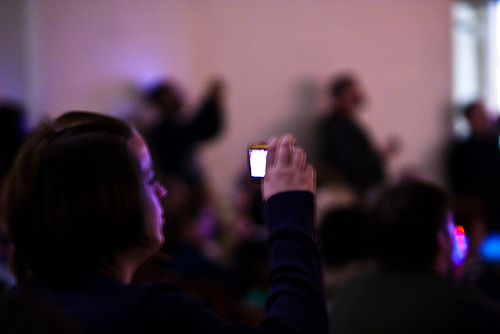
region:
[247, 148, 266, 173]
light from a camera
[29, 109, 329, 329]
a person holding a camera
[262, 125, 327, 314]
a person's hand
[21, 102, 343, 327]
a person standing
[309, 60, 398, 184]
a person standing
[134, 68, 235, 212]
a person standing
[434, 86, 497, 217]
a person standing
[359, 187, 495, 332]
a person standing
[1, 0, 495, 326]
it is a nighttime scene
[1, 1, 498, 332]
the picture is blurry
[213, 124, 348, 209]
The lady is taking a selfie.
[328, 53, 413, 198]
A man is leaning against the wall.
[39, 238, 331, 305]
The lady has on a blue sweater.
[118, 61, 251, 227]
A person is taking a picture with cellphone.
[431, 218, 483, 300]
A man is holding a cell phone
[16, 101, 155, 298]
The lady has brown hair.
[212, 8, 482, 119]
The wall is white.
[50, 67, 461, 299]
People in a room taking pictures.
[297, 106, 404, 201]
the man is wearing a dark colored jacket.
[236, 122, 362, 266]
The lady is holding a cell phone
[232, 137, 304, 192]
Woman holding a cell phone.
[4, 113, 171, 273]
The woman has brown hair.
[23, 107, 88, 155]
Woman is wearing a barrette.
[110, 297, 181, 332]
The shirt is blue.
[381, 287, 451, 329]
Man is wearing a grey shirt.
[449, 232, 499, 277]
Blue light in front of the man.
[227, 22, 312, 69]
The wall is beige.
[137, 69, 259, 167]
Man holding up a phone.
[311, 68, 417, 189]
Man leaning against a wall.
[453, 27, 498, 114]
Light coming through a window.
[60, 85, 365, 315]
a woman is taking a picture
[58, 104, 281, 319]
woman is holding a camera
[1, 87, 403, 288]
a woman is watching a show or performance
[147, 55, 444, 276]
the audience watching the performance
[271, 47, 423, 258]
blurry people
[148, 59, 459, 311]
people are paying attention to the speaker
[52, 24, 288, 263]
people are standing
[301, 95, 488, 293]
people are sitting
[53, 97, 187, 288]
a brunette is watching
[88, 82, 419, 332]
people are watching attentively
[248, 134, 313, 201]
woman taking picture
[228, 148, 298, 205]
screen is bright and white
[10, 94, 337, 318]
woman is standing uo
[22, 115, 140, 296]
wona has short hair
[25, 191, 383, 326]
woman is wearing blue sweater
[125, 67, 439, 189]
people are leaning against wall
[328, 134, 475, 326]
some people are sitting down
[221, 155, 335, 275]
womans sweater is lon sleeved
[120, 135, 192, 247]
glow reflecting on womans face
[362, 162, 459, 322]
man with brown hair